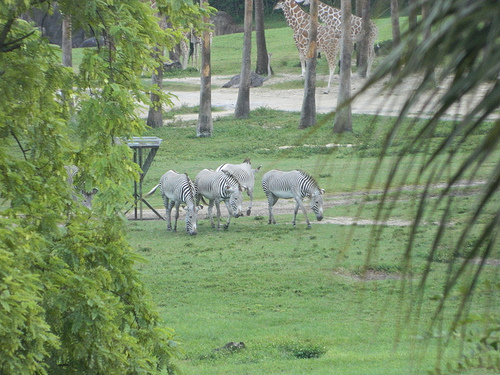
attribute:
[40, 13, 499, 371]
grass — short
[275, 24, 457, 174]
leaf — long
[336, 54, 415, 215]
leaf — long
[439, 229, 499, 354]
leaf — long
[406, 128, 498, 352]
leaf — long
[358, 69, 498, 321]
leaf — long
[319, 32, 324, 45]
spot — brown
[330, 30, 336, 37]
spot — brown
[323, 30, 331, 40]
spot — brown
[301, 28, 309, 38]
spot — brown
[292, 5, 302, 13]
spot — brown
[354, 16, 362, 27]
spot — brown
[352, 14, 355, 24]
spot — brown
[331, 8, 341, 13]
spot — brown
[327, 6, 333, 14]
spot — brown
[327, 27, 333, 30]
spot — brown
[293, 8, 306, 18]
spot — brown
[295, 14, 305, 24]
spot — brown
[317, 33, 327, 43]
spot — brown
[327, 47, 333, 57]
spot — brown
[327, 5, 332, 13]
spot — brown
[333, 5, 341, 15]
spot — brown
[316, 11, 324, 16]
spot — brown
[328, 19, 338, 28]
spot — brown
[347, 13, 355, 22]
spot — brown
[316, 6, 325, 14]
spot — brown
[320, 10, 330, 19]
spot — brown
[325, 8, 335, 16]
spot — brown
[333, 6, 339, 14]
spot — brown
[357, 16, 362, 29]
spot — brown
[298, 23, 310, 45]
spot — brown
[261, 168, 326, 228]
zebra — grazing, together, standing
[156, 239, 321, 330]
area — of green grass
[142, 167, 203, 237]
zebra — together, grazing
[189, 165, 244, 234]
zebra — together, grazing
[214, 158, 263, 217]
zebra — together, grazing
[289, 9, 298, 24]
spot — brown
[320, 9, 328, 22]
spot — brown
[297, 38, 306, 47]
spot — brown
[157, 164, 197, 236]
zebra — four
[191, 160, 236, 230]
zebra — four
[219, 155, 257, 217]
zebra — four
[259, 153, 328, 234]
zebra — four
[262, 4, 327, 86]
giraffe — tall, one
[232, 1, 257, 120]
tree trunk — slender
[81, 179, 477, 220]
path — small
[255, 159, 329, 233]
zebra — eating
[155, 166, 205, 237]
zebra — one, eating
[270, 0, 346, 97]
giraffe — tall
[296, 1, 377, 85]
giraffe — tall